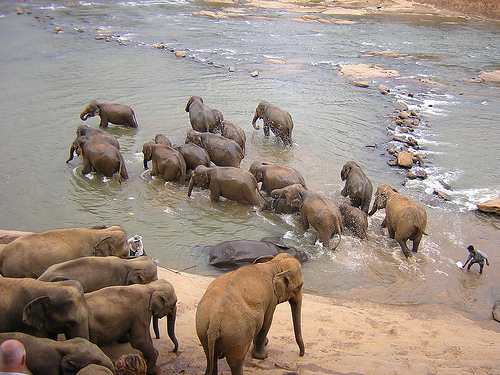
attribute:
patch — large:
[340, 62, 402, 81]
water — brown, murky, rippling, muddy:
[0, 0, 499, 335]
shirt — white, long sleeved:
[465, 249, 490, 262]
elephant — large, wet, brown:
[187, 164, 270, 207]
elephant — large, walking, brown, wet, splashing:
[270, 182, 345, 253]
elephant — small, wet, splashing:
[338, 202, 370, 243]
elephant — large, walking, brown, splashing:
[369, 184, 431, 262]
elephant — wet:
[340, 160, 375, 215]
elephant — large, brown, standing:
[195, 251, 306, 374]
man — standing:
[128, 234, 149, 258]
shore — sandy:
[0, 227, 499, 373]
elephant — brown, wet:
[80, 99, 138, 130]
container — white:
[455, 260, 465, 270]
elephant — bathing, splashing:
[209, 237, 309, 269]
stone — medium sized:
[173, 50, 188, 59]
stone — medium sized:
[15, 6, 26, 16]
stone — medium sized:
[53, 26, 63, 33]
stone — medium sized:
[228, 65, 236, 73]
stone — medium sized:
[250, 69, 260, 77]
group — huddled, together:
[67, 95, 431, 273]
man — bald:
[1, 338, 27, 374]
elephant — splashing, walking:
[251, 99, 295, 148]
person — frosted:
[113, 352, 149, 374]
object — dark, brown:
[415, 54, 441, 61]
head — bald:
[1, 338, 27, 374]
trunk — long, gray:
[288, 293, 306, 357]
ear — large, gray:
[20, 293, 51, 332]